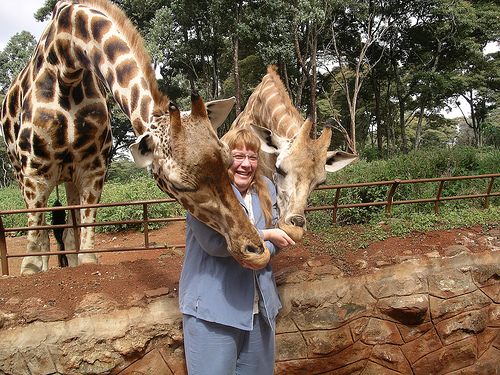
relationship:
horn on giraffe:
[168, 105, 181, 134] [15, 8, 272, 290]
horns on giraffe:
[292, 113, 336, 146] [228, 64, 359, 240]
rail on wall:
[44, 181, 148, 275] [47, 300, 140, 360]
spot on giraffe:
[102, 37, 129, 64] [2, 3, 267, 315]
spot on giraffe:
[114, 57, 141, 88] [15, 8, 272, 290]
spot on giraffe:
[48, 29, 107, 72] [9, 17, 283, 267]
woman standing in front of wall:
[172, 119, 299, 374] [35, 179, 195, 254]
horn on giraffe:
[168, 105, 181, 134] [23, 21, 215, 218]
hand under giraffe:
[224, 216, 303, 262] [228, 53, 353, 250]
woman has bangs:
[172, 119, 299, 374] [227, 130, 263, 149]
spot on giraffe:
[106, 42, 127, 61] [218, 61, 355, 236]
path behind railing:
[0, 222, 190, 276] [2, 167, 499, 275]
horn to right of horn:
[192, 89, 207, 118] [317, 125, 331, 149]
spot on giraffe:
[33, 42, 48, 73] [147, 101, 349, 276]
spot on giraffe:
[41, 40, 74, 81] [8, 20, 241, 240]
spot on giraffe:
[123, 81, 140, 115] [8, 20, 241, 240]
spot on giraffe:
[140, 77, 158, 86] [8, 20, 241, 240]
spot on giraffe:
[104, 35, 130, 67] [8, 20, 241, 240]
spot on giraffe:
[24, 176, 34, 189] [8, 20, 241, 240]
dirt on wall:
[1, 234, 323, 334] [5, 230, 493, 374]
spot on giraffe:
[74, 123, 99, 139] [38, 15, 228, 260]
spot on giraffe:
[17, 69, 39, 99] [15, 8, 272, 290]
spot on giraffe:
[15, 120, 32, 150] [2, 3, 267, 315]